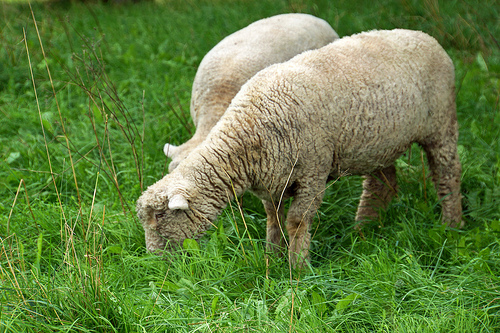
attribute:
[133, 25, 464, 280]
sheep — standing still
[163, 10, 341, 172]
sheep — standing still